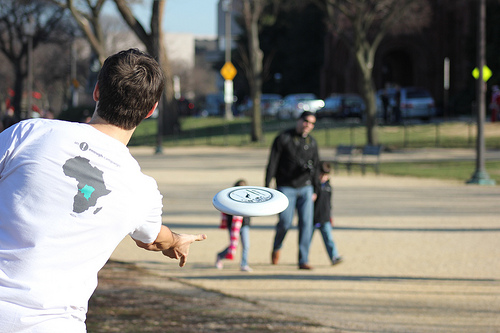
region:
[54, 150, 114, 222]
Map of Africa in black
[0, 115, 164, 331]
A white t-shirt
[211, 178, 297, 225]
A white frisbee being tossed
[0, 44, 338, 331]
Four people in the park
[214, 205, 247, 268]
A pink and white scarf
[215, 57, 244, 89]
A yellow road sign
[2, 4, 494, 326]
This is a picture of a park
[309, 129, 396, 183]
Two benches in the park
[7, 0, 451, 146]
Bare trees lining the walkway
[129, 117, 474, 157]
A black fence along the park border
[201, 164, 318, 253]
White frisbee in the air.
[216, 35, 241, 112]
Orange street sign.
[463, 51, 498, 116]
Yellow street sign.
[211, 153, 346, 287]
Two children walking.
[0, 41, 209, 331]
Person wearing a white shirt.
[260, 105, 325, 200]
Person wearing a black shirt.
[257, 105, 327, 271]
Person wearing brown shoes.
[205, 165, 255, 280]
Girl wearing a pink scarf.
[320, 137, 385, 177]
Blue bench next to grass.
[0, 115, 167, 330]
Africa on a shirt.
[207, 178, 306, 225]
white Frisbee in flight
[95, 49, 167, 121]
man's freshly cut black hair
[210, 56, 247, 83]
yellow triangular street sign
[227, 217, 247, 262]
portion of red and white stripe scarf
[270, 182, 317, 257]
man wearing blue jeans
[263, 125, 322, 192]
man wearing shiny black jacket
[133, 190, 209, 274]
man's arm outstretched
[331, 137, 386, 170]
wire park bench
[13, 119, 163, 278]
man's white tee shirt with Africa symbol on back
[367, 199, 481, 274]
large clean asphalt pavement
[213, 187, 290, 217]
frisbee flying.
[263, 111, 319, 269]
man walking with children.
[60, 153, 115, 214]
map of Africa on the shirt.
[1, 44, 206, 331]
boy throws frisbee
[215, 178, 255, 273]
girl walking with the man.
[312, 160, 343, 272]
boy walking with man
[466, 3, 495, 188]
light pole on the curb.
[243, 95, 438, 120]
cars lining the street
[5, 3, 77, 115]
trees with no leaves.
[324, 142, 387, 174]
park bench along the street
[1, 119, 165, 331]
bright white t-shirt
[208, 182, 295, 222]
white frisbe in the air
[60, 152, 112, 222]
picture of Africa on t-shirt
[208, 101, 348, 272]
a man and his children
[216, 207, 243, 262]
little girl's pink striped scarf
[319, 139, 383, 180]
two benches behind family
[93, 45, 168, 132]
man has brown hair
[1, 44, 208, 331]
man throwing a frisbe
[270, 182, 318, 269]
man has blue jeans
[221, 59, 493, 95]
two yellow signs in background